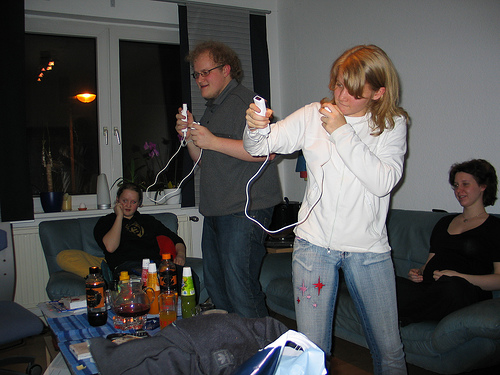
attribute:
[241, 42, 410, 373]
woman — playing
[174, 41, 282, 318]
man — playing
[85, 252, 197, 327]
bottles — grouped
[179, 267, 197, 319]
bottle — green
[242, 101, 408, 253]
shirt — white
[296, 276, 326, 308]
design — pink, red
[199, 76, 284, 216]
shirt — grey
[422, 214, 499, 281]
top — black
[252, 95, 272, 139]
wiimote — white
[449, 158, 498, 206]
hair — brown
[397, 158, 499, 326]
lady — sitting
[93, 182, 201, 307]
girl — sitting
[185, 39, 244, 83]
hair — blonde, wavy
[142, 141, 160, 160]
orchid — purple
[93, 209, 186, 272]
shirt — black